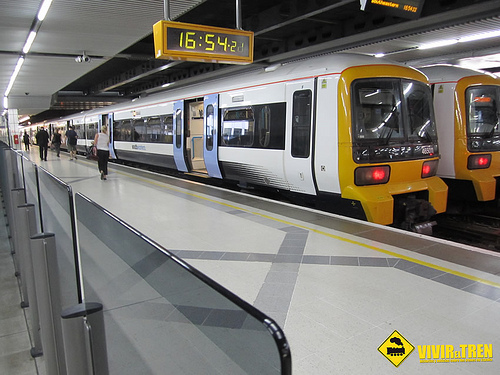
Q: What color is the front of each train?
A: Yellow.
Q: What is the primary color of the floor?
A: White.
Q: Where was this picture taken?
A: A subway station.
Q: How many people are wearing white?
A: One.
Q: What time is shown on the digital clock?
A: 16:54:21.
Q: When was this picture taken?
A: Afternoon.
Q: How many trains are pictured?
A: Two.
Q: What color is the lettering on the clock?
A: Yellow.